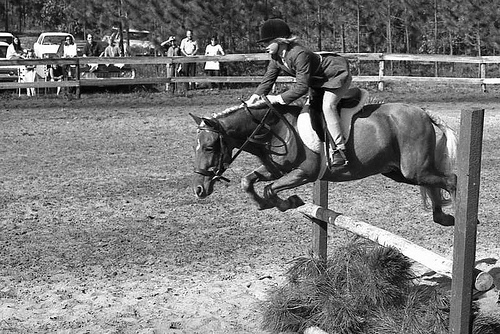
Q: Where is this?
A: This is at the field.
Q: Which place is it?
A: It is a field.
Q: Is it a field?
A: Yes, it is a field.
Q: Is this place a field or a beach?
A: It is a field.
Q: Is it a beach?
A: No, it is a field.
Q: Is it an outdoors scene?
A: Yes, it is outdoors.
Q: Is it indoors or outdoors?
A: It is outdoors.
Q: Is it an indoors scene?
A: No, it is outdoors.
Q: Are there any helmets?
A: Yes, there is a helmet.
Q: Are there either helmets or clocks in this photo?
A: Yes, there is a helmet.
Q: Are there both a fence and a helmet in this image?
A: Yes, there are both a helmet and a fence.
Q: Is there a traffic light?
A: No, there are no traffic lights.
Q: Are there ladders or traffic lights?
A: No, there are no traffic lights or ladders.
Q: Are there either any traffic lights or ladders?
A: No, there are no traffic lights or ladders.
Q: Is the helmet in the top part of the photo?
A: Yes, the helmet is in the top of the image.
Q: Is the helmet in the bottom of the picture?
A: No, the helmet is in the top of the image.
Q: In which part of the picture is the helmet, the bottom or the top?
A: The helmet is in the top of the image.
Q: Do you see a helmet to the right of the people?
A: Yes, there is a helmet to the right of the people.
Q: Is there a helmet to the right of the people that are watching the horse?
A: Yes, there is a helmet to the right of the people.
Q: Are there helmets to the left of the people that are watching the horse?
A: No, the helmet is to the right of the people.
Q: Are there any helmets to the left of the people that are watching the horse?
A: No, the helmet is to the right of the people.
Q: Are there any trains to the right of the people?
A: No, there is a helmet to the right of the people.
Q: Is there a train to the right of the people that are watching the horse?
A: No, there is a helmet to the right of the people.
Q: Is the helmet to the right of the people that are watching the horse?
A: Yes, the helmet is to the right of the people.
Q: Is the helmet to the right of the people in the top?
A: Yes, the helmet is to the right of the people.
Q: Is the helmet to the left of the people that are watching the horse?
A: No, the helmet is to the right of the people.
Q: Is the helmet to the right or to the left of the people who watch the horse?
A: The helmet is to the right of the people.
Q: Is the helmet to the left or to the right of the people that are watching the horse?
A: The helmet is to the right of the people.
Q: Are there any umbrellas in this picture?
A: No, there are no umbrellas.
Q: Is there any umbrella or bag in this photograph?
A: No, there are no umbrellas or bags.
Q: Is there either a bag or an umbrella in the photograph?
A: No, there are no umbrellas or bags.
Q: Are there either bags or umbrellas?
A: No, there are no umbrellas or bags.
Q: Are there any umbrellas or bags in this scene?
A: No, there are no umbrellas or bags.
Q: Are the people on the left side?
A: Yes, the people are on the left of the image.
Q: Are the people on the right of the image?
A: No, the people are on the left of the image.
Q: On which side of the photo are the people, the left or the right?
A: The people are on the left of the image.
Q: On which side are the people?
A: The people are on the left of the image.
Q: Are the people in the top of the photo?
A: Yes, the people are in the top of the image.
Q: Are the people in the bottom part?
A: No, the people are in the top of the image.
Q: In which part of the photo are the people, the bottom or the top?
A: The people are in the top of the image.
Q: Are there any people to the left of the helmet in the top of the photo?
A: Yes, there are people to the left of the helmet.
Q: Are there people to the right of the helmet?
A: No, the people are to the left of the helmet.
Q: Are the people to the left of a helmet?
A: Yes, the people are to the left of a helmet.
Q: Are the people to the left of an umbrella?
A: No, the people are to the left of a helmet.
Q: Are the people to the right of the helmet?
A: No, the people are to the left of the helmet.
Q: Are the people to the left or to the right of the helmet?
A: The people are to the left of the helmet.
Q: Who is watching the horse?
A: The people are watching the horse.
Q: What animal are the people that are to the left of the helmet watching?
A: The people are watching the horse.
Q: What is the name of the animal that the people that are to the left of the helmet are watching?
A: The animal is a horse.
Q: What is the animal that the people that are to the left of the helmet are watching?
A: The animal is a horse.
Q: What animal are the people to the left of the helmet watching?
A: The people are watching the horse.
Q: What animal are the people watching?
A: The people are watching the horse.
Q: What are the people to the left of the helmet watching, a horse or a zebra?
A: The people are watching a horse.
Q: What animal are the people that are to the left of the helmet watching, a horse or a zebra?
A: The people are watching a horse.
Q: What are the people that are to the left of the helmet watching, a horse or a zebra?
A: The people are watching a horse.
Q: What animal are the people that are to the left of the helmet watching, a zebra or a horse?
A: The people are watching a horse.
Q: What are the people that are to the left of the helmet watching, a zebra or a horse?
A: The people are watching a horse.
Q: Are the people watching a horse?
A: Yes, the people are watching a horse.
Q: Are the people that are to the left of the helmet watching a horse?
A: Yes, the people are watching a horse.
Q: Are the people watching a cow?
A: No, the people are watching a horse.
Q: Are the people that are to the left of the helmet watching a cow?
A: No, the people are watching a horse.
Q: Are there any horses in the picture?
A: Yes, there is a horse.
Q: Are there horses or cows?
A: Yes, there is a horse.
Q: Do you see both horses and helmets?
A: Yes, there are both a horse and a helmet.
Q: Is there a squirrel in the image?
A: No, there are no squirrels.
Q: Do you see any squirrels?
A: No, there are no squirrels.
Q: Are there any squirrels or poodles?
A: No, there are no squirrels or poodles.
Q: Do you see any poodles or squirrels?
A: No, there are no squirrels or poodles.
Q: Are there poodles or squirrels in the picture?
A: No, there are no squirrels or poodles.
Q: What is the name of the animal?
A: The animal is a horse.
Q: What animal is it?
A: The animal is a horse.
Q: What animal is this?
A: This is a horse.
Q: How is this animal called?
A: This is a horse.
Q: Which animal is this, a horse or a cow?
A: This is a horse.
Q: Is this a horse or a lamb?
A: This is a horse.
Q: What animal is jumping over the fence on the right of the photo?
A: The horse is jumping over the fence.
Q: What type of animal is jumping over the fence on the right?
A: The animal is a horse.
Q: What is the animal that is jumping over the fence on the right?
A: The animal is a horse.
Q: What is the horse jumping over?
A: The horse is jumping over the fence.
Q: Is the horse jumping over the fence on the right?
A: Yes, the horse is jumping over the fence.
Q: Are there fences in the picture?
A: Yes, there is a fence.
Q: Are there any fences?
A: Yes, there is a fence.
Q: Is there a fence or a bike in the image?
A: Yes, there is a fence.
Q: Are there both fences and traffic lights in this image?
A: No, there is a fence but no traffic lights.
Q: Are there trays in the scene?
A: No, there are no trays.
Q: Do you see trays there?
A: No, there are no trays.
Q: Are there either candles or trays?
A: No, there are no trays or candles.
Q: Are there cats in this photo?
A: No, there are no cats.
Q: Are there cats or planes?
A: No, there are no cats or planes.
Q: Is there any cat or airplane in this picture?
A: No, there are no cats or airplanes.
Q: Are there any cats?
A: No, there are no cats.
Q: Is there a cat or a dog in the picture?
A: No, there are no cats or dogs.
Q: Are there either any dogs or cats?
A: No, there are no cats or dogs.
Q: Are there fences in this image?
A: Yes, there is a fence.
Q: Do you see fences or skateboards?
A: Yes, there is a fence.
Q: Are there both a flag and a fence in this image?
A: No, there is a fence but no flags.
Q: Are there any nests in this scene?
A: No, there are no nests.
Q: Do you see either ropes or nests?
A: No, there are no nests or ropes.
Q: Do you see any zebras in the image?
A: No, there are no zebras.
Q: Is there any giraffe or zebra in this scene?
A: No, there are no zebras or giraffes.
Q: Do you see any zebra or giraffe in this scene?
A: No, there are no zebras or giraffes.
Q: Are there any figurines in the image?
A: No, there are no figurines.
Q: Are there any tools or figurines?
A: No, there are no figurines or tools.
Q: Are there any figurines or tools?
A: No, there are no figurines or tools.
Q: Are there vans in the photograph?
A: No, there are no vans.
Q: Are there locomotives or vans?
A: No, there are no vans or locomotives.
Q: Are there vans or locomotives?
A: No, there are no vans or locomotives.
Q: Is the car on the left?
A: Yes, the car is on the left of the image.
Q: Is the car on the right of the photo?
A: No, the car is on the left of the image.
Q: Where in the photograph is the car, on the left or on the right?
A: The car is on the left of the image.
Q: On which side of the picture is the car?
A: The car is on the left of the image.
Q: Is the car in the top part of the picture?
A: Yes, the car is in the top of the image.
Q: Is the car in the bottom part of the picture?
A: No, the car is in the top of the image.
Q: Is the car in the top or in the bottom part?
A: The car is in the top of the image.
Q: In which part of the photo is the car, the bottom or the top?
A: The car is in the top of the image.